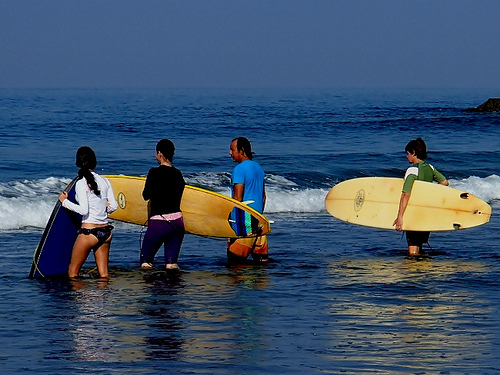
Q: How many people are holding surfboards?
A: 3.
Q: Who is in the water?
A: Surfers.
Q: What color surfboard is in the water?
A: Blue.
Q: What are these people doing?
A: Standing in the water.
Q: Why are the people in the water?
A: Wading.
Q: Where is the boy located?
A: To the far right.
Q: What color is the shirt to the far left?
A: White.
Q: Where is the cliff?
A: In the far right.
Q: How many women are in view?
A: 2.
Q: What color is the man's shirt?
A: Blue.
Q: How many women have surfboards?
A: Two.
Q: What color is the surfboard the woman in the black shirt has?
A: Yellow with striped logo.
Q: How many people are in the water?
A: Four.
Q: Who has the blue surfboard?
A: Woman in white shirt.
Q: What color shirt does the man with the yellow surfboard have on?
A: Green and white.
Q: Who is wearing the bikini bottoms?
A: Woman in white shirt.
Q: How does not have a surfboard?
A: Man in blue shirt.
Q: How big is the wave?
A: Small.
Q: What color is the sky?
A: Blue.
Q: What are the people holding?
A: Surfboards.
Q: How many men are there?
A: Two.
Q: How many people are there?
A: Four.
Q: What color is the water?
A: Blue.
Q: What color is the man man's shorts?
A: Rainbow.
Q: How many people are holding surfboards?
A: Three.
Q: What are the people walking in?
A: The ocean.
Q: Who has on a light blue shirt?
A: The man.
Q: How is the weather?
A: Clear.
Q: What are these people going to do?
A: Surf.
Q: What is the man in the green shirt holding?
A: A surfboard.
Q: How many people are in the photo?
A: Four.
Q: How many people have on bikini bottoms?
A: One.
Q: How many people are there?
A: Four.